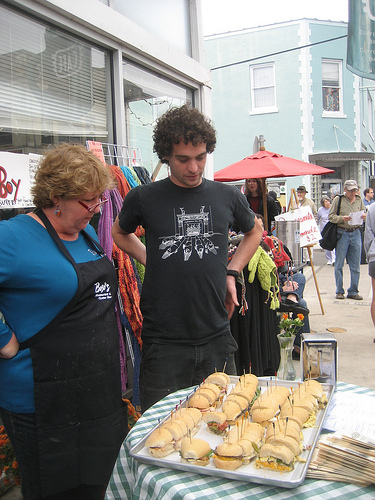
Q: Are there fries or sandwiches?
A: Yes, there is a sandwich.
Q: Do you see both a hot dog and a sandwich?
A: No, there is a sandwich but no hot dogs.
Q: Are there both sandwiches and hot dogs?
A: No, there is a sandwich but no hot dogs.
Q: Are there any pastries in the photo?
A: No, there are no pastries.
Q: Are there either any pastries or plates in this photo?
A: No, there are no pastries or plates.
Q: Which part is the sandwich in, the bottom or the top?
A: The sandwich is in the bottom of the image.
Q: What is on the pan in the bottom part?
A: The sandwich is on the pan.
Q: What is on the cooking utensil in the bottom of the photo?
A: The sandwich is on the pan.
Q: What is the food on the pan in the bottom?
A: The food is a sandwich.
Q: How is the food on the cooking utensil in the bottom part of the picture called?
A: The food is a sandwich.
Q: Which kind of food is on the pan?
A: The food is a sandwich.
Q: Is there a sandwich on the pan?
A: Yes, there is a sandwich on the pan.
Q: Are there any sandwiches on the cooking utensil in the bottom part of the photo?
A: Yes, there is a sandwich on the pan.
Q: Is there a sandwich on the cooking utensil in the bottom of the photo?
A: Yes, there is a sandwich on the pan.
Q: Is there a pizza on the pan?
A: No, there is a sandwich on the pan.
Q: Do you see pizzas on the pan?
A: No, there is a sandwich on the pan.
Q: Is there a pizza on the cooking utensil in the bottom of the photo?
A: No, there is a sandwich on the pan.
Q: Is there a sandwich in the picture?
A: Yes, there is a sandwich.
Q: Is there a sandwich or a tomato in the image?
A: Yes, there is a sandwich.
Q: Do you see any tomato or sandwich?
A: Yes, there is a sandwich.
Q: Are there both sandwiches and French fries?
A: No, there is a sandwich but no fries.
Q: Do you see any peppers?
A: No, there are no peppers.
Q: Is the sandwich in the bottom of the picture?
A: Yes, the sandwich is in the bottom of the image.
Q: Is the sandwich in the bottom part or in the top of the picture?
A: The sandwich is in the bottom of the image.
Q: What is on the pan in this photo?
A: The sandwich is on the pan.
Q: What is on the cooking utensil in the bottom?
A: The sandwich is on the pan.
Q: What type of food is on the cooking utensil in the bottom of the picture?
A: The food is a sandwich.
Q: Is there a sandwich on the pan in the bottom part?
A: Yes, there is a sandwich on the pan.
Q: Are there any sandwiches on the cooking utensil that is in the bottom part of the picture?
A: Yes, there is a sandwich on the pan.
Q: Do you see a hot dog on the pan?
A: No, there is a sandwich on the pan.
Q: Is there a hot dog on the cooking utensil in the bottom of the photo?
A: No, there is a sandwich on the pan.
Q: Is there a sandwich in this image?
A: Yes, there is a sandwich.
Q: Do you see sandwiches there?
A: Yes, there is a sandwich.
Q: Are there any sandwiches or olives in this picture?
A: Yes, there is a sandwich.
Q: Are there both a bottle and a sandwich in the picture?
A: No, there is a sandwich but no bottles.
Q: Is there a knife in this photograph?
A: No, there are no knives.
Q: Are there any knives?
A: No, there are no knives.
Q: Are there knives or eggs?
A: No, there are no knives or eggs.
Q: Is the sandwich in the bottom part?
A: Yes, the sandwich is in the bottom of the image.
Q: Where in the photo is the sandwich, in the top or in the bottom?
A: The sandwich is in the bottom of the image.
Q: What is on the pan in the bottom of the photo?
A: The sandwich is on the pan.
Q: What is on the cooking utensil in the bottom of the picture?
A: The sandwich is on the pan.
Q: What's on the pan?
A: The sandwich is on the pan.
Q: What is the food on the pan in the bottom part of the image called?
A: The food is a sandwich.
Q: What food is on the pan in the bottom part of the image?
A: The food is a sandwich.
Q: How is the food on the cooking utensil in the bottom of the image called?
A: The food is a sandwich.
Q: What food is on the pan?
A: The food is a sandwich.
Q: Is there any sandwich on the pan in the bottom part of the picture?
A: Yes, there is a sandwich on the pan.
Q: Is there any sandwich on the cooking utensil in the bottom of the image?
A: Yes, there is a sandwich on the pan.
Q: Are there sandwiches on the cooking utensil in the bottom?
A: Yes, there is a sandwich on the pan.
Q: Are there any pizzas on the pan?
A: No, there is a sandwich on the pan.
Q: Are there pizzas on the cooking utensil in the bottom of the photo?
A: No, there is a sandwich on the pan.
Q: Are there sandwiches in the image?
A: Yes, there is a sandwich.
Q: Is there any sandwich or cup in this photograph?
A: Yes, there is a sandwich.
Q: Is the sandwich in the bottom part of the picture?
A: Yes, the sandwich is in the bottom of the image.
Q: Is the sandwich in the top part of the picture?
A: No, the sandwich is in the bottom of the image.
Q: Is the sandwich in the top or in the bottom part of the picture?
A: The sandwich is in the bottom of the image.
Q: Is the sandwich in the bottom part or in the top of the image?
A: The sandwich is in the bottom of the image.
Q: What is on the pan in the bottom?
A: The sandwich is on the pan.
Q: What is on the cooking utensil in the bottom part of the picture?
A: The sandwich is on the pan.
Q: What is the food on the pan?
A: The food is a sandwich.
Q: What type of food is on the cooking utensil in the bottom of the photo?
A: The food is a sandwich.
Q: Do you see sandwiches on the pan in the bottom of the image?
A: Yes, there is a sandwich on the pan.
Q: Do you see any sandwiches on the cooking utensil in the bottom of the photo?
A: Yes, there is a sandwich on the pan.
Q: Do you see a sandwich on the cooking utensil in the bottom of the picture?
A: Yes, there is a sandwich on the pan.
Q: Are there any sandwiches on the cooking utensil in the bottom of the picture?
A: Yes, there is a sandwich on the pan.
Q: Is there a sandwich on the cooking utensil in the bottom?
A: Yes, there is a sandwich on the pan.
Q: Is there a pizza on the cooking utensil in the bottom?
A: No, there is a sandwich on the pan.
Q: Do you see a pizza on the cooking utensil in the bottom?
A: No, there is a sandwich on the pan.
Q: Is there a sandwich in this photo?
A: Yes, there is a sandwich.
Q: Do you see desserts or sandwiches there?
A: Yes, there is a sandwich.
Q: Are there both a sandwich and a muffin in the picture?
A: No, there is a sandwich but no muffins.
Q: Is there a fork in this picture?
A: No, there are no forks.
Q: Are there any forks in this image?
A: No, there are no forks.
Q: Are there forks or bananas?
A: No, there are no forks or bananas.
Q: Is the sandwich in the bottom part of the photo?
A: Yes, the sandwich is in the bottom of the image.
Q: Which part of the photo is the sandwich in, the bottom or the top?
A: The sandwich is in the bottom of the image.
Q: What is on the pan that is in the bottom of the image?
A: The sandwich is on the pan.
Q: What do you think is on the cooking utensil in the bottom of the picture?
A: The sandwich is on the pan.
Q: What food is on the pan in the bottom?
A: The food is a sandwich.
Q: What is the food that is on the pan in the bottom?
A: The food is a sandwich.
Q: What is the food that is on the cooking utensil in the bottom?
A: The food is a sandwich.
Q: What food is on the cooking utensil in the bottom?
A: The food is a sandwich.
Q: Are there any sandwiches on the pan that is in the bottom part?
A: Yes, there is a sandwich on the pan.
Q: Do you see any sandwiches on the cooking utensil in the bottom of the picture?
A: Yes, there is a sandwich on the pan.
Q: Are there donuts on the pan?
A: No, there is a sandwich on the pan.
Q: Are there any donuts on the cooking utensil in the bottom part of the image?
A: No, there is a sandwich on the pan.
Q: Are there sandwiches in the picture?
A: Yes, there is a sandwich.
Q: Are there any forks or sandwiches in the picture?
A: Yes, there is a sandwich.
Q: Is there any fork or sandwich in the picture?
A: Yes, there is a sandwich.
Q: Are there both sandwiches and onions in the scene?
A: No, there is a sandwich but no onions.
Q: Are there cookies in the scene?
A: No, there are no cookies.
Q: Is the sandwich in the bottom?
A: Yes, the sandwich is in the bottom of the image.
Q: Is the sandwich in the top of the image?
A: No, the sandwich is in the bottom of the image.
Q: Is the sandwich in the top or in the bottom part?
A: The sandwich is in the bottom of the image.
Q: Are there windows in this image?
A: Yes, there is a window.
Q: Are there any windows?
A: Yes, there is a window.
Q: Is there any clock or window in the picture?
A: Yes, there is a window.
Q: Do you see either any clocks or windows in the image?
A: Yes, there is a window.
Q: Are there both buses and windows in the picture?
A: No, there is a window but no buses.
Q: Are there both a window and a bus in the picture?
A: No, there is a window but no buses.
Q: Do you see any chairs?
A: No, there are no chairs.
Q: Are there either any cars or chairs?
A: No, there are no chairs or cars.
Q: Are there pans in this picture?
A: Yes, there is a pan.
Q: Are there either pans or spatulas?
A: Yes, there is a pan.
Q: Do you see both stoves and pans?
A: No, there is a pan but no stoves.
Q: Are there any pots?
A: No, there are no pots.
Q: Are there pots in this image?
A: No, there are no pots.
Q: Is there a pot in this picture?
A: No, there are no pots.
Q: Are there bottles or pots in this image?
A: No, there are no pots or bottles.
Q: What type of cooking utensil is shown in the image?
A: The cooking utensil is a pan.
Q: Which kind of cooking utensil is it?
A: The cooking utensil is a pan.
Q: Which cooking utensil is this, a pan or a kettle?
A: This is a pan.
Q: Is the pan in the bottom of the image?
A: Yes, the pan is in the bottom of the image.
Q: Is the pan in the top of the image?
A: No, the pan is in the bottom of the image.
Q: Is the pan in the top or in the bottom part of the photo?
A: The pan is in the bottom of the image.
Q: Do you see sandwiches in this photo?
A: Yes, there is a sandwich.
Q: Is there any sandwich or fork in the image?
A: Yes, there is a sandwich.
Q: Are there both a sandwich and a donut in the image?
A: No, there is a sandwich but no donuts.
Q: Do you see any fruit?
A: No, there are no fruits.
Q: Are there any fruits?
A: No, there are no fruits.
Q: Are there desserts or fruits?
A: No, there are no fruits or desserts.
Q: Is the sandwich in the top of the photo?
A: No, the sandwich is in the bottom of the image.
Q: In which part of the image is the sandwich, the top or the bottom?
A: The sandwich is in the bottom of the image.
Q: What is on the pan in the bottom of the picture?
A: The sandwich is on the pan.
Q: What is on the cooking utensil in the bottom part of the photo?
A: The sandwich is on the pan.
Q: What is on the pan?
A: The sandwich is on the pan.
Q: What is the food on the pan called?
A: The food is a sandwich.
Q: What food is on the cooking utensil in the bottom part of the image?
A: The food is a sandwich.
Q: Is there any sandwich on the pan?
A: Yes, there is a sandwich on the pan.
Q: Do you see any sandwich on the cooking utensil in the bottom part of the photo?
A: Yes, there is a sandwich on the pan.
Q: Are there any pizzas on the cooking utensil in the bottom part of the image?
A: No, there is a sandwich on the pan.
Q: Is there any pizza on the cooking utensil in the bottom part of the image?
A: No, there is a sandwich on the pan.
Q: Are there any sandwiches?
A: Yes, there is a sandwich.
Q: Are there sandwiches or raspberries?
A: Yes, there is a sandwich.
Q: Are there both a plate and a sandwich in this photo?
A: No, there is a sandwich but no plates.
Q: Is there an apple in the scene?
A: No, there are no apples.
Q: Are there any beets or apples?
A: No, there are no apples or beets.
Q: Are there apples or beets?
A: No, there are no apples or beets.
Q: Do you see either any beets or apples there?
A: No, there are no apples or beets.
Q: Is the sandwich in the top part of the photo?
A: No, the sandwich is in the bottom of the image.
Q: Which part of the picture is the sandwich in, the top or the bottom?
A: The sandwich is in the bottom of the image.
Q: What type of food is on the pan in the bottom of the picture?
A: The food is a sandwich.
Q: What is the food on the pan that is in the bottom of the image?
A: The food is a sandwich.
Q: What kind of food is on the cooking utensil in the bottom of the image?
A: The food is a sandwich.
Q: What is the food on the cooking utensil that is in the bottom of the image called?
A: The food is a sandwich.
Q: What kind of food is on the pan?
A: The food is a sandwich.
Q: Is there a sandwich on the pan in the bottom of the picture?
A: Yes, there is a sandwich on the pan.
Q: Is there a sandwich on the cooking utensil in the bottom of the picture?
A: Yes, there is a sandwich on the pan.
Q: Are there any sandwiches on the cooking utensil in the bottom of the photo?
A: Yes, there is a sandwich on the pan.